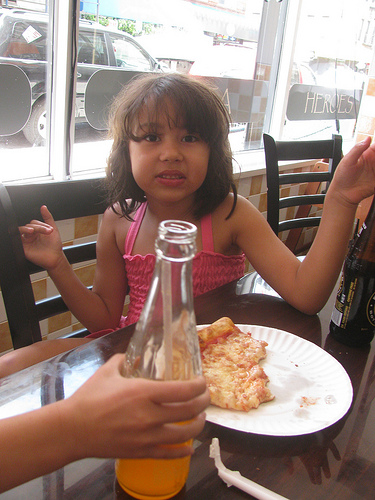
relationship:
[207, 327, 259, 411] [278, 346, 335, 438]
pizza on top of plate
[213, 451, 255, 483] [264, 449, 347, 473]
wrapper on top of table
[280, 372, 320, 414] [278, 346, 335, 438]
grease on top of plate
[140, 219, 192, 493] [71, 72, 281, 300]
bottle near girl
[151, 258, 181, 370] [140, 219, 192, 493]
straw inside of bottle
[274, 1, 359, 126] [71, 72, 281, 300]
window behind girl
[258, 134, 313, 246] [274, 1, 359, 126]
chair in front of window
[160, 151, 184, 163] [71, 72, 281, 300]
nose attached to girl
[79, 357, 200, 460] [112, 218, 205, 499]
hand wrapped around bottle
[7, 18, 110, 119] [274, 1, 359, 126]
car outside of window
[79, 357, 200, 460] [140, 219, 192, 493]
hand holding onto bottle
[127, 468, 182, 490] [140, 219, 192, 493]
liquid inside of bottle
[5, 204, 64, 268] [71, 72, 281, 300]
hands attached to girl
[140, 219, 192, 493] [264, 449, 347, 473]
bottle on top of table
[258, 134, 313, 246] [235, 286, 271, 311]
chair next to a table